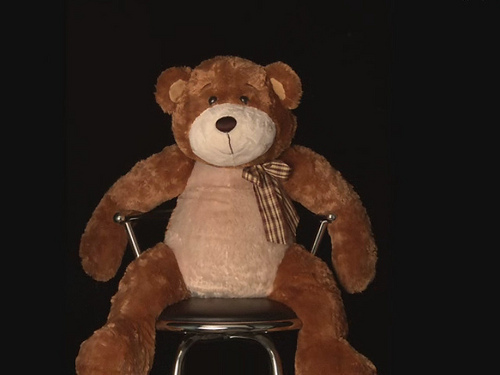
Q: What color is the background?
A: Black.